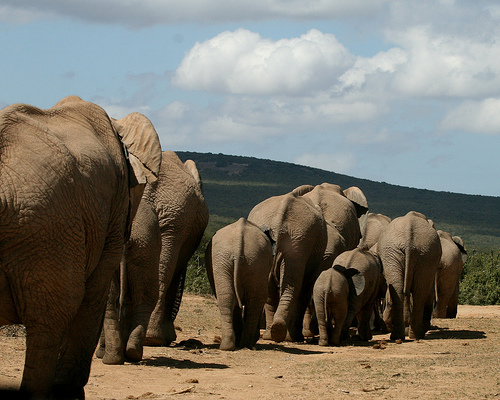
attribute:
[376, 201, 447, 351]
elephant — grey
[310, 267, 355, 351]
elephant — baby, tiny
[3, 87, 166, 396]
elephant — adult, grey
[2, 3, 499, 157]
day — cloudy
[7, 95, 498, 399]
landscape — natural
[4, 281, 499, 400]
terrain — brown, dirt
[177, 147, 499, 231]
mountain — green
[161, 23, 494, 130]
clouds — white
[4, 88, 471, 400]
elephants — group, different size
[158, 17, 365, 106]
cloud — white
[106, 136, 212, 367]
elephant — adult